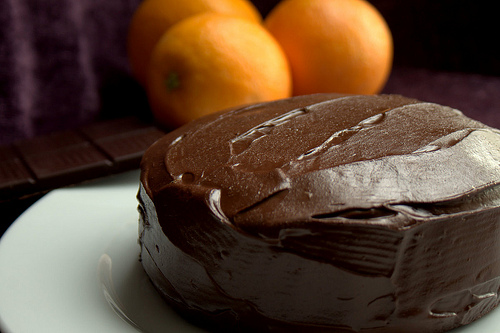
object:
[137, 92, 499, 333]
icing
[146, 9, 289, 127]
orange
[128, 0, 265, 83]
orange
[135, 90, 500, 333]
cake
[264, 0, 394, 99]
orange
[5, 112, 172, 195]
bars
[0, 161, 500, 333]
plate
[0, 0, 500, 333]
table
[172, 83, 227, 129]
wall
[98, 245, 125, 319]
light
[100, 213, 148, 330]
plate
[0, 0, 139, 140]
fabric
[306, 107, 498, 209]
frosting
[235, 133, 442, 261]
dark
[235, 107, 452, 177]
chocolate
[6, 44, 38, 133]
purple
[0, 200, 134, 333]
white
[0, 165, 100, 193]
left corner